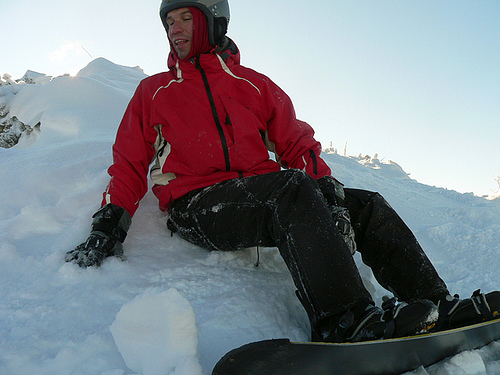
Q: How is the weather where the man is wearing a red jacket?
A: Freezing cold.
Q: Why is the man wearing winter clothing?
A: To keep warm while snowboarding.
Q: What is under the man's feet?
A: A snowboard.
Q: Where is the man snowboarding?
A: Top of a mountain.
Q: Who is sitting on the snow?
A: A man in a red coat.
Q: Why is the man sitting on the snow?
A: Accidentally slipped and fell.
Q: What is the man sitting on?
A: Snow.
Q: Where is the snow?
A: On the mountain.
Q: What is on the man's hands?
A: Winter gloves.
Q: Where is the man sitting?
A: In the snow.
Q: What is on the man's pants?
A: Snow.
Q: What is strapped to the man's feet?
A: Snowboard.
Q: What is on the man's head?
A: Helmet.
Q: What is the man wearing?
A: Red jacket.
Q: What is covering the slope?
A: Snow.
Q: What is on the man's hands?
A: Gloves.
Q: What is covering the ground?
A: Snow.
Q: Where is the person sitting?
A: Snow hill.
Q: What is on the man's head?
A: Hat.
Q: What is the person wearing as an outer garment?
A: Red jacket.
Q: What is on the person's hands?
A: Black gloves.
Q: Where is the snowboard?
A: By the man's feet.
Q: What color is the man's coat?
A: Red.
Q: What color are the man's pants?
A: Black.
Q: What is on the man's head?
A: A helmet.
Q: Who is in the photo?
A: The man.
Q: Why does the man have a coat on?
A: It is cold.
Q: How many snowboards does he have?
A: One.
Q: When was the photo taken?
A: Winter.